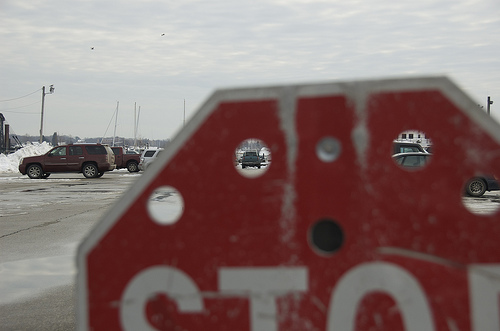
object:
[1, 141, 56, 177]
snow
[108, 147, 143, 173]
pick-up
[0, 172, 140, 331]
ground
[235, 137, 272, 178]
hole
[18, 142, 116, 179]
car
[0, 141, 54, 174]
pile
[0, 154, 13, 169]
white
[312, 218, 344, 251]
black circle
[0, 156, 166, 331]
road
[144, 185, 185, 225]
holes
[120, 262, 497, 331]
lettering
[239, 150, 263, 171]
cars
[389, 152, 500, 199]
cars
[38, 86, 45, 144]
pole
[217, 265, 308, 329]
white t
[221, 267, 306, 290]
top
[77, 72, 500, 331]
sign